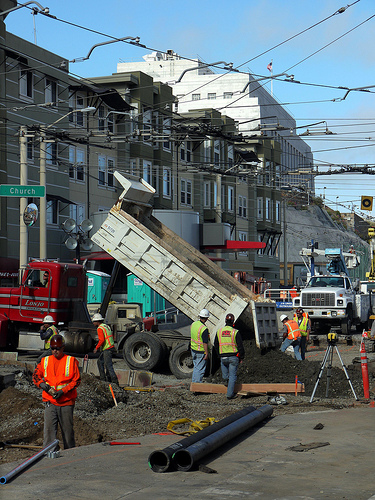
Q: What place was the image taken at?
A: It was taken at the street.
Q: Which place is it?
A: It is a street.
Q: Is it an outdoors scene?
A: Yes, it is outdoors.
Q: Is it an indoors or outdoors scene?
A: It is outdoors.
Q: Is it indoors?
A: No, it is outdoors.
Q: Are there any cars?
A: No, there are no cars.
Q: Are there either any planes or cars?
A: No, there are no cars or planes.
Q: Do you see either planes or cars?
A: No, there are no cars or planes.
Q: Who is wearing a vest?
A: The worker is wearing a vest.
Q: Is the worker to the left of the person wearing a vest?
A: Yes, the worker is wearing a vest.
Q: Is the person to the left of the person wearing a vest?
A: Yes, the worker is wearing a vest.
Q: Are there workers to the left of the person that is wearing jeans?
A: Yes, there is a worker to the left of the person.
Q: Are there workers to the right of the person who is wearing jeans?
A: No, the worker is to the left of the person.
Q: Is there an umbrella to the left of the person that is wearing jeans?
A: No, there is a worker to the left of the person.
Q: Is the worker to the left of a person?
A: Yes, the worker is to the left of a person.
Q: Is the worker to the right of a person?
A: No, the worker is to the left of a person.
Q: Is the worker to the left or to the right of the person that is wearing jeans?
A: The worker is to the left of the person.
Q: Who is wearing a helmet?
A: The worker is wearing a helmet.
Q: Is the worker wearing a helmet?
A: Yes, the worker is wearing a helmet.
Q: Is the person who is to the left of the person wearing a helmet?
A: Yes, the worker is wearing a helmet.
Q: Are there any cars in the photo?
A: No, there are no cars.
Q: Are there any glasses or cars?
A: No, there are no cars or glasses.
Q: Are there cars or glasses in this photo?
A: No, there are no cars or glasses.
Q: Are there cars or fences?
A: No, there are no cars or fences.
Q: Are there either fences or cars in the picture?
A: No, there are no cars or fences.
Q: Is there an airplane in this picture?
A: No, there are no airplanes.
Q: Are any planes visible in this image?
A: No, there are no planes.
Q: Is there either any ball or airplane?
A: No, there are no airplanes or balls.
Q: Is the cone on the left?
A: No, the cone is on the right of the image.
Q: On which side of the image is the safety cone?
A: The safety cone is on the right of the image.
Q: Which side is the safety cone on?
A: The safety cone is on the right of the image.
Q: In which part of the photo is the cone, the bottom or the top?
A: The cone is in the bottom of the image.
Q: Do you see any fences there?
A: No, there are no fences.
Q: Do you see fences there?
A: No, there are no fences.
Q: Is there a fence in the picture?
A: No, there are no fences.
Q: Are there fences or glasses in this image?
A: No, there are no fences or glasses.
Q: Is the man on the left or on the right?
A: The man is on the left of the image.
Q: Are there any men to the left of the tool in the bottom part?
A: Yes, there is a man to the left of the tool.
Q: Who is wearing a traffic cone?
A: The man is wearing a traffic cone.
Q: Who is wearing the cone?
A: The man is wearing a traffic cone.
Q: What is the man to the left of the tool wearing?
A: The man is wearing a cone.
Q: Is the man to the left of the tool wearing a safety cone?
A: Yes, the man is wearing a safety cone.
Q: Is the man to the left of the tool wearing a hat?
A: No, the man is wearing a safety cone.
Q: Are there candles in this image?
A: No, there are no candles.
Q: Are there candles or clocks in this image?
A: No, there are no candles or clocks.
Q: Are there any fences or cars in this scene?
A: No, there are no fences or cars.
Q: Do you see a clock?
A: No, there are no clocks.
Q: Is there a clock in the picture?
A: No, there are no clocks.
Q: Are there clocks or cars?
A: No, there are no clocks or cars.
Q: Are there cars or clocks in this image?
A: No, there are no clocks or cars.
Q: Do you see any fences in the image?
A: No, there are no fences.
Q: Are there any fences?
A: No, there are no fences.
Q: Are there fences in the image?
A: No, there are no fences.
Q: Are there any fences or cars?
A: No, there are no fences or cars.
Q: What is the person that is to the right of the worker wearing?
A: The person is wearing jeans.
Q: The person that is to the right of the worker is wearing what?
A: The person is wearing jeans.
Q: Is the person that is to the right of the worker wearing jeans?
A: Yes, the person is wearing jeans.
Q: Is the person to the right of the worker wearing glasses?
A: No, the person is wearing jeans.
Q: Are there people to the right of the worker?
A: Yes, there is a person to the right of the worker.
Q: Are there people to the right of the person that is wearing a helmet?
A: Yes, there is a person to the right of the worker.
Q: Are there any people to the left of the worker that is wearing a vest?
A: No, the person is to the right of the worker.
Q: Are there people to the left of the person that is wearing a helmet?
A: No, the person is to the right of the worker.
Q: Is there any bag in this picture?
A: No, there are no bags.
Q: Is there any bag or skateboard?
A: No, there are no bags or skateboards.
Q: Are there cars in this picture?
A: No, there are no cars.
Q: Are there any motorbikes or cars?
A: No, there are no cars or motorbikes.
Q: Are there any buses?
A: No, there are no buses.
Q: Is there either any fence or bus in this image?
A: No, there are no buses or fences.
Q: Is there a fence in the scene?
A: No, there are no fences.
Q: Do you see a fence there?
A: No, there are no fences.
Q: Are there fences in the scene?
A: No, there are no fences.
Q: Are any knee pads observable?
A: No, there are no knee pads.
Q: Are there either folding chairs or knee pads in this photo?
A: No, there are no knee pads or folding chairs.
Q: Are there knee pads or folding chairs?
A: No, there are no knee pads or folding chairs.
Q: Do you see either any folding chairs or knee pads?
A: No, there are no knee pads or folding chairs.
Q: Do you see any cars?
A: No, there are no cars.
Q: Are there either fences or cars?
A: No, there are no cars or fences.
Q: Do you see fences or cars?
A: No, there are no cars or fences.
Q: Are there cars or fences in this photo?
A: No, there are no cars or fences.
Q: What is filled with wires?
A: The sky is filled with wires.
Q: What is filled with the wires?
A: The sky is filled with wires.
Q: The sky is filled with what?
A: The sky is filled with wires.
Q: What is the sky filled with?
A: The sky is filled with wires.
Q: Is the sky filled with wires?
A: Yes, the sky is filled with wires.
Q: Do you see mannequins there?
A: No, there are no mannequins.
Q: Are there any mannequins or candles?
A: No, there are no mannequins or candles.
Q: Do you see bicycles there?
A: No, there are no bicycles.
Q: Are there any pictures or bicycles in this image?
A: No, there are no bicycles or pictures.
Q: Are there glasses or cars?
A: No, there are no cars or glasses.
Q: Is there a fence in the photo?
A: No, there are no fences.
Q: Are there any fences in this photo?
A: No, there are no fences.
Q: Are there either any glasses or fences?
A: No, there are no fences or glasses.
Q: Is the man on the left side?
A: Yes, the man is on the left of the image.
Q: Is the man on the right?
A: No, the man is on the left of the image.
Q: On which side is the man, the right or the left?
A: The man is on the left of the image.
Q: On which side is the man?
A: The man is on the left of the image.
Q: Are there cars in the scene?
A: No, there are no cars.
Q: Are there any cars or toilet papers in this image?
A: No, there are no cars or toilet papers.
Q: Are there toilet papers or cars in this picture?
A: No, there are no cars or toilet papers.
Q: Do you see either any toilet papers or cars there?
A: No, there are no cars or toilet papers.